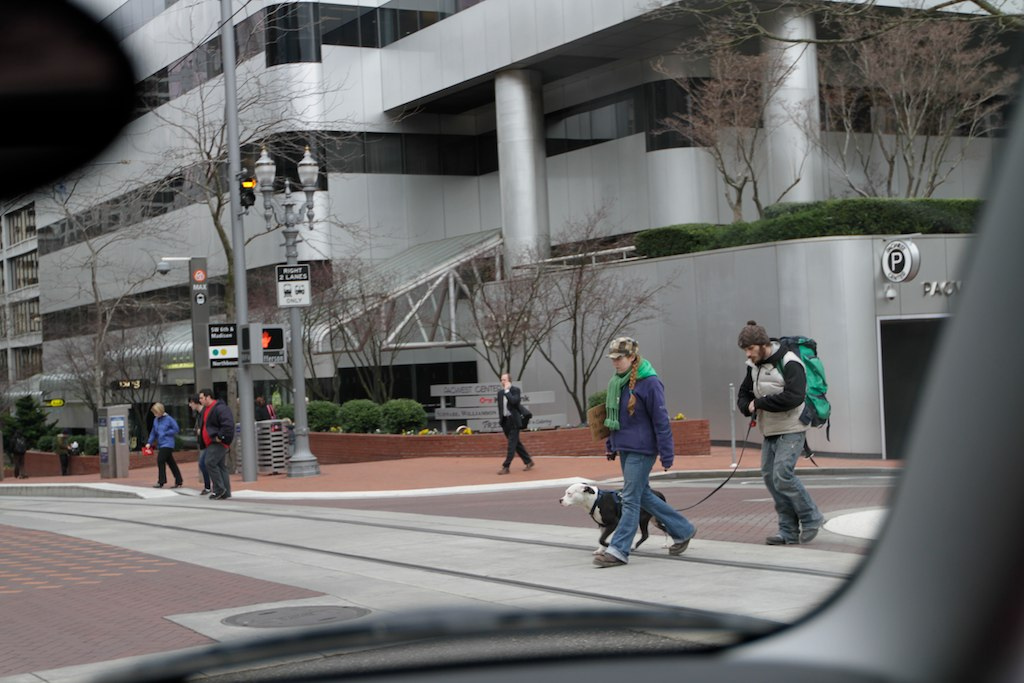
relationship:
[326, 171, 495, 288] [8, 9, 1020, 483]
wall on side of building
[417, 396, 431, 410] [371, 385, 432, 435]
leaves on tree